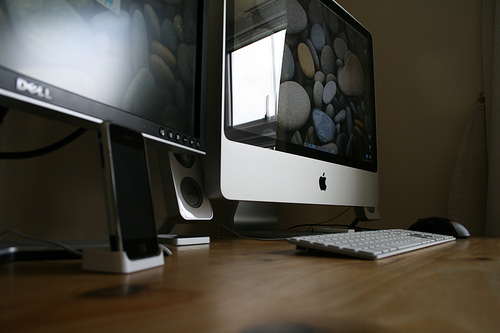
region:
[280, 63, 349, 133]
rocks on the monitor screen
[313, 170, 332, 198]
black apple logo on the monitor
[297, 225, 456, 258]
white keyboard on the desk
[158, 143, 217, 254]
grey speaker on the desk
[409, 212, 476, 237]
black and grey computer mouse on the desk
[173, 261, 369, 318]
tan and brown wood of the desk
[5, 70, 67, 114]
silver lettering on the monitor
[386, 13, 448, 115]
white walls of the room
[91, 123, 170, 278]
black phone on a white stand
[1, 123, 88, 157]
black power cord of the monitor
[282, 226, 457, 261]
Computer low profile keyboard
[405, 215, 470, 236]
Black computer mouse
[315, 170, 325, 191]
Apple Inc. black on silver logo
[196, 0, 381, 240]
Flat screen computer monitor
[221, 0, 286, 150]
A reflection of a window off a monitor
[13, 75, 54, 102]
Official Dell computer logo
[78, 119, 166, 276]
Cell phone sitting in a white charger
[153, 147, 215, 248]
Computer speaker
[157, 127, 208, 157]
Setting panel for a computer monitor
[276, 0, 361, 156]
Picture of assorted rocks on desktop monitor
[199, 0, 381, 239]
an Apple iMac computer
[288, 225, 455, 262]
an Apple USB keyboard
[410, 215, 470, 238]
a black and silver mouse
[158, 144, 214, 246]
a silver computer speaker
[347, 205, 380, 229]
a silver computer speaker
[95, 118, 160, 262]
a black Apple iPhone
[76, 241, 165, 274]
a white iPhone dock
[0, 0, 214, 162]
a black framed computer monitor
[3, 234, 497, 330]
a light brown desk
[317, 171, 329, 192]
a black Apple corporate logo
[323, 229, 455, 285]
a white computer keyboard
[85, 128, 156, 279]
a cell phone in a phone dock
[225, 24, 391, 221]
a computer monitor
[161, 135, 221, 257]
a black and silver computer speaker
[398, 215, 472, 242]
a black and silver computer mouse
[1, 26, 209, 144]
a dell computer monitor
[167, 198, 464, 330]
a wood desk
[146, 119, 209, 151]
control buttons on a monitor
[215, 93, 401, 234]
a apple computer monitor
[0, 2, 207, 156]
A Dell computer screen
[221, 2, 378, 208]
An apple computer screen.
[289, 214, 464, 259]
A computer mouse and keyboard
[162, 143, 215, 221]
A computer speaker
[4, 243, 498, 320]
A wooden computer desk.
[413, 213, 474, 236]
A computer mouse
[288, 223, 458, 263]
A computer keyboard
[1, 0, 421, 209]
A pair of computers on a desk.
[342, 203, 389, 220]
A computer speaker on a desk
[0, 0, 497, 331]
A computer office.